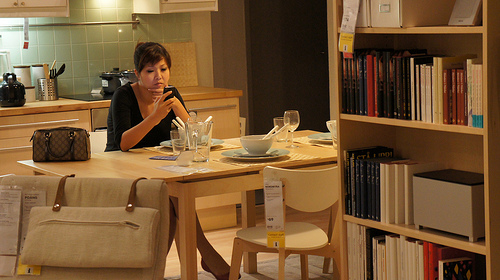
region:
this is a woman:
[75, 28, 315, 195]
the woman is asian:
[88, 40, 223, 98]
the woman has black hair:
[124, 34, 188, 59]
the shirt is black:
[84, 77, 192, 149]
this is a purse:
[25, 115, 77, 172]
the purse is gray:
[5, 104, 110, 155]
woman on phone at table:
[110, 43, 206, 186]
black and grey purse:
[24, 116, 97, 166]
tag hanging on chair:
[255, 170, 302, 263]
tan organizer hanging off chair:
[43, 167, 190, 273]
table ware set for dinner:
[147, 109, 352, 161]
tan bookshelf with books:
[338, 49, 480, 239]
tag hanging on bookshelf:
[331, 10, 359, 68]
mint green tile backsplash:
[18, 29, 98, 72]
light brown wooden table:
[113, 149, 318, 249]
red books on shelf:
[351, 50, 383, 127]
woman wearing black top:
[102, 83, 187, 165]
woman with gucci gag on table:
[27, 121, 95, 166]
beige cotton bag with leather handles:
[17, 173, 179, 271]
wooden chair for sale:
[223, 158, 347, 278]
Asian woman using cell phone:
[104, 37, 197, 144]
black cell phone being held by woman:
[161, 83, 182, 112]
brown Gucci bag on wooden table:
[23, 121, 96, 168]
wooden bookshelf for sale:
[322, 5, 499, 279]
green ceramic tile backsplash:
[3, 0, 189, 90]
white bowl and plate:
[218, 133, 293, 162]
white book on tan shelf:
[408, 56, 415, 119]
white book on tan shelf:
[465, 57, 473, 127]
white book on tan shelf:
[470, 63, 478, 126]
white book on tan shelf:
[400, 157, 402, 223]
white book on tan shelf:
[414, 63, 421, 120]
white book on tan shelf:
[418, 64, 425, 121]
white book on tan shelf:
[423, 65, 431, 120]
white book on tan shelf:
[345, 219, 351, 277]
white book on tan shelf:
[370, 236, 377, 276]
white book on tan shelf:
[387, 237, 397, 279]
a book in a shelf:
[403, 163, 434, 217]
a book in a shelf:
[393, 162, 404, 217]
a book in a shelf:
[438, 256, 468, 278]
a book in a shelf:
[438, 245, 456, 277]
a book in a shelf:
[429, 245, 447, 277]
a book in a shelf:
[419, 238, 438, 278]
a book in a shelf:
[386, 230, 396, 278]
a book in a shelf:
[378, 243, 388, 278]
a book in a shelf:
[374, 237, 377, 277]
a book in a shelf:
[361, 230, 377, 278]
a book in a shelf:
[433, 248, 459, 266]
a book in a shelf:
[428, 244, 433, 279]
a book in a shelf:
[421, 238, 429, 276]